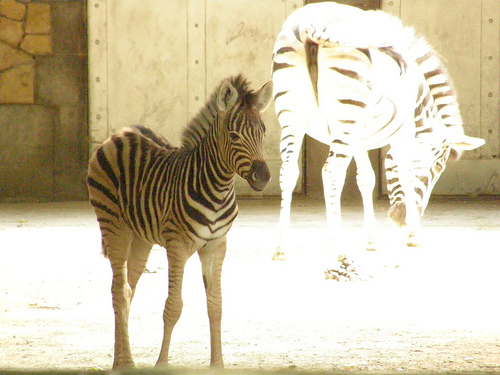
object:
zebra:
[86, 71, 275, 373]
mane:
[180, 97, 214, 151]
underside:
[129, 225, 166, 246]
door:
[85, 0, 205, 157]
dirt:
[279, 260, 357, 342]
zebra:
[270, 0, 486, 261]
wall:
[3, 4, 87, 149]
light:
[276, 229, 413, 331]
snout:
[248, 167, 271, 185]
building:
[0, 0, 499, 205]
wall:
[200, 8, 264, 77]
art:
[0, 0, 66, 111]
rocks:
[325, 248, 365, 289]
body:
[96, 138, 211, 246]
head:
[213, 73, 272, 192]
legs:
[103, 229, 137, 369]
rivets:
[90, 0, 104, 10]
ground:
[0, 196, 499, 374]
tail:
[300, 8, 416, 49]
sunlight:
[260, 227, 321, 347]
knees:
[162, 296, 183, 321]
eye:
[229, 131, 242, 143]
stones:
[8, 213, 34, 231]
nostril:
[252, 171, 264, 181]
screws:
[94, 35, 103, 51]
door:
[380, 0, 499, 196]